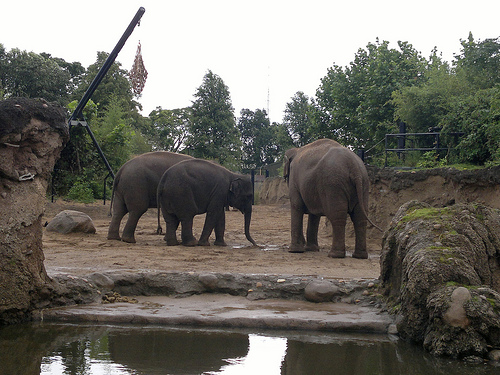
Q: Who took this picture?
A: Cameraman.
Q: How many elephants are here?
A: Three.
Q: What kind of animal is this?
A: Elephant.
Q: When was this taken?
A: Daytime.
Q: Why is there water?
A: For them to drink.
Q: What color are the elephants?
A: Grey.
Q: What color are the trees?
A: Green.